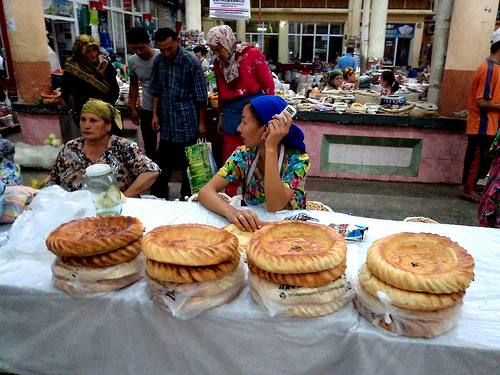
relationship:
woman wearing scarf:
[208, 97, 301, 213] [254, 153, 305, 183]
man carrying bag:
[134, 26, 214, 178] [175, 65, 198, 109]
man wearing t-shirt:
[457, 39, 499, 204] [124, 49, 157, 113]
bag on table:
[8, 187, 89, 248] [1, 181, 497, 374]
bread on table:
[244, 220, 352, 318] [11, 160, 499, 371]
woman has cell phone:
[196, 94, 301, 236] [276, 105, 299, 124]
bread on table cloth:
[44, 212, 146, 294] [0, 189, 499, 375]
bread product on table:
[366, 230, 474, 292] [1, 181, 497, 374]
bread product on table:
[366, 230, 479, 293] [1, 181, 497, 374]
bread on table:
[244, 220, 346, 273] [1, 181, 497, 374]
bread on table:
[140, 222, 239, 266] [1, 181, 497, 374]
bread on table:
[44, 212, 137, 257] [1, 181, 497, 374]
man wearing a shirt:
[454, 17, 499, 167] [462, 62, 499, 144]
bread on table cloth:
[140, 222, 240, 266] [0, 189, 499, 375]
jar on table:
[80, 162, 121, 216] [1, 181, 497, 374]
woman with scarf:
[196, 94, 301, 236] [248, 91, 313, 135]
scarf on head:
[248, 91, 313, 135] [218, 102, 313, 154]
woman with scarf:
[50, 97, 161, 197] [80, 97, 122, 130]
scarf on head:
[80, 97, 122, 130] [80, 98, 112, 138]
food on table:
[290, 88, 430, 115] [295, 107, 463, 182]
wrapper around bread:
[48, 260, 141, 304] [50, 218, 141, 263]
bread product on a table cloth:
[366, 230, 479, 293] [0, 189, 499, 375]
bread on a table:
[44, 212, 137, 257] [1, 181, 497, 374]